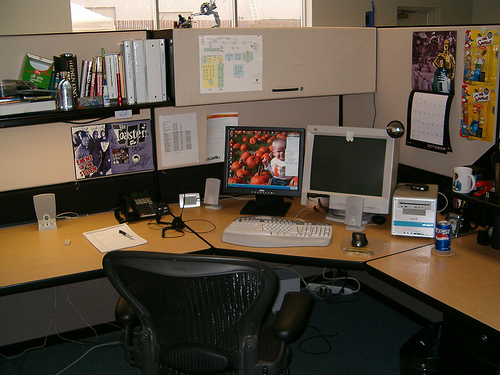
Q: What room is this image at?
A: It is at the office.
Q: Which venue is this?
A: This is an office.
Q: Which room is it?
A: It is an office.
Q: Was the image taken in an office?
A: Yes, it was taken in an office.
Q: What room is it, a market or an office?
A: It is an office.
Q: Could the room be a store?
A: No, it is an office.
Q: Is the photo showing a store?
A: No, the picture is showing an office.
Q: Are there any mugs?
A: Yes, there is a mug.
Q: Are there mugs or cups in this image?
A: Yes, there is a mug.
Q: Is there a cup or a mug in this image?
A: Yes, there is a mug.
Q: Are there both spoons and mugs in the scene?
A: No, there is a mug but no spoons.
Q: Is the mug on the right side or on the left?
A: The mug is on the right of the image.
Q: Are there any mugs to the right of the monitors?
A: Yes, there is a mug to the right of the monitors.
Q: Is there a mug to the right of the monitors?
A: Yes, there is a mug to the right of the monitors.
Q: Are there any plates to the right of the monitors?
A: No, there is a mug to the right of the monitors.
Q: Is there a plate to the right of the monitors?
A: No, there is a mug to the right of the monitors.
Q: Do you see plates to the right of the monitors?
A: No, there is a mug to the right of the monitors.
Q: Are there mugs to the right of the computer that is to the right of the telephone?
A: Yes, there is a mug to the right of the computer.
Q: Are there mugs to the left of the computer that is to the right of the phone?
A: No, the mug is to the right of the computer.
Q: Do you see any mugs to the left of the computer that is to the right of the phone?
A: No, the mug is to the right of the computer.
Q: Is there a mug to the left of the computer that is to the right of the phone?
A: No, the mug is to the right of the computer.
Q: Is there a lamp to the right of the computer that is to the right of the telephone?
A: No, there is a mug to the right of the computer.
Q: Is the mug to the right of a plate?
A: No, the mug is to the right of the computer.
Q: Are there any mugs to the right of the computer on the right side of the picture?
A: Yes, there is a mug to the right of the computer.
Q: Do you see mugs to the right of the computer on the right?
A: Yes, there is a mug to the right of the computer.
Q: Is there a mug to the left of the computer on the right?
A: No, the mug is to the right of the computer.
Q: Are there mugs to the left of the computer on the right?
A: No, the mug is to the right of the computer.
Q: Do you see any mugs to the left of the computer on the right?
A: No, the mug is to the right of the computer.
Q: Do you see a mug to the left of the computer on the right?
A: No, the mug is to the right of the computer.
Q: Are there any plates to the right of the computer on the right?
A: No, there is a mug to the right of the computer.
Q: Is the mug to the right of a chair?
A: No, the mug is to the right of a computer.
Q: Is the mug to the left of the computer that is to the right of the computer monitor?
A: No, the mug is to the right of the computer.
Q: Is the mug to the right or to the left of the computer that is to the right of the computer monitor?
A: The mug is to the right of the computer.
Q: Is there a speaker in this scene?
A: Yes, there is a speaker.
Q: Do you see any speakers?
A: Yes, there is a speaker.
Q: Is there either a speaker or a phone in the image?
A: Yes, there is a speaker.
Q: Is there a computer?
A: Yes, there is a computer.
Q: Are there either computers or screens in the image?
A: Yes, there is a computer.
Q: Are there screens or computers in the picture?
A: Yes, there is a computer.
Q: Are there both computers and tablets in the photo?
A: No, there is a computer but no tablets.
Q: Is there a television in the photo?
A: No, there are no televisions.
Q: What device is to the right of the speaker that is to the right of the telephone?
A: The device is a computer.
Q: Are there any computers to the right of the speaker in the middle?
A: Yes, there is a computer to the right of the speaker.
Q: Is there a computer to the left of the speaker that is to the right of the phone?
A: No, the computer is to the right of the speaker.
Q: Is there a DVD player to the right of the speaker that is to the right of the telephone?
A: No, there is a computer to the right of the speaker.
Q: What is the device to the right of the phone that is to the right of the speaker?
A: The device is a computer.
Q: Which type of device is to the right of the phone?
A: The device is a computer.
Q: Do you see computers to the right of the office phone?
A: Yes, there is a computer to the right of the phone.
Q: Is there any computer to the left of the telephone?
A: No, the computer is to the right of the telephone.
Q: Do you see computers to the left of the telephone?
A: No, the computer is to the right of the telephone.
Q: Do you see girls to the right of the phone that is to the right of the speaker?
A: No, there is a computer to the right of the phone.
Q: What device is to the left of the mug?
A: The device is a computer.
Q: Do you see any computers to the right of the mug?
A: No, the computer is to the left of the mug.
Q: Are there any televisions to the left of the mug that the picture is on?
A: No, there is a computer to the left of the mug.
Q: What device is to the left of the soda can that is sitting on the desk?
A: The device is a computer.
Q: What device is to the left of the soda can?
A: The device is a computer.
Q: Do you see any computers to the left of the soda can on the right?
A: Yes, there is a computer to the left of the soda can.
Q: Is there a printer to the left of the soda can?
A: No, there is a computer to the left of the soda can.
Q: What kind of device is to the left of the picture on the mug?
A: The device is a computer.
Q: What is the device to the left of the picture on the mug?
A: The device is a computer.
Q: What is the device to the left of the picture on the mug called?
A: The device is a computer.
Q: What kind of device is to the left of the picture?
A: The device is a computer.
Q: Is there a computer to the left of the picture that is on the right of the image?
A: Yes, there is a computer to the left of the picture.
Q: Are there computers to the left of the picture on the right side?
A: Yes, there is a computer to the left of the picture.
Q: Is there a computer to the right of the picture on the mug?
A: No, the computer is to the left of the picture.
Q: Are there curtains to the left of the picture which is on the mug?
A: No, there is a computer to the left of the picture.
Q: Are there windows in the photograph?
A: Yes, there is a window.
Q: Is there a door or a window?
A: Yes, there is a window.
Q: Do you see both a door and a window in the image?
A: No, there is a window but no doors.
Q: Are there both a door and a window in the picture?
A: No, there is a window but no doors.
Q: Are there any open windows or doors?
A: Yes, there is an open window.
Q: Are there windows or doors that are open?
A: Yes, the window is open.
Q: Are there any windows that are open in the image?
A: Yes, there is an open window.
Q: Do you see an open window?
A: Yes, there is an open window.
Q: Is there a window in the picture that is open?
A: Yes, there is a window that is open.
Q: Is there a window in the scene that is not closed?
A: Yes, there is a open window.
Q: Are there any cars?
A: No, there are no cars.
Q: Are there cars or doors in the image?
A: No, there are no cars or doors.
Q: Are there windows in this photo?
A: Yes, there is a window.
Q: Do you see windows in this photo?
A: Yes, there is a window.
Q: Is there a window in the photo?
A: Yes, there is a window.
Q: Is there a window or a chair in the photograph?
A: Yes, there is a window.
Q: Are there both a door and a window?
A: No, there is a window but no doors.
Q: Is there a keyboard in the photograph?
A: Yes, there is a keyboard.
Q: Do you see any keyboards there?
A: Yes, there is a keyboard.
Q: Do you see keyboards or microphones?
A: Yes, there is a keyboard.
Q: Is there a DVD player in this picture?
A: No, there are no DVD players.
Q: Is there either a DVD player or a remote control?
A: No, there are no DVD players or remote controls.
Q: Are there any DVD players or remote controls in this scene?
A: No, there are no DVD players or remote controls.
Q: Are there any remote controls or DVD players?
A: No, there are no DVD players or remote controls.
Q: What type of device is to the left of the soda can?
A: The device is a keyboard.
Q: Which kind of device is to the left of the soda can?
A: The device is a keyboard.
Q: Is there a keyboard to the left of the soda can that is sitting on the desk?
A: Yes, there is a keyboard to the left of the soda can.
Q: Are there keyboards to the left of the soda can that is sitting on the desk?
A: Yes, there is a keyboard to the left of the soda can.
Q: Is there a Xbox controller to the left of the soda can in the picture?
A: No, there is a keyboard to the left of the soda can.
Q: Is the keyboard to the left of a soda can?
A: Yes, the keyboard is to the left of a soda can.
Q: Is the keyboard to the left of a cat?
A: No, the keyboard is to the left of a soda can.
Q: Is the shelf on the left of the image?
A: Yes, the shelf is on the left of the image.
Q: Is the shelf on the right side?
A: No, the shelf is on the left of the image.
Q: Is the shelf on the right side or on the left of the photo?
A: The shelf is on the left of the image.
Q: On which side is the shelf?
A: The shelf is on the left of the image.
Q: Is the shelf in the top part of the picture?
A: Yes, the shelf is in the top of the image.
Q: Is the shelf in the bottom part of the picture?
A: No, the shelf is in the top of the image.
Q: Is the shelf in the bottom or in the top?
A: The shelf is in the top of the image.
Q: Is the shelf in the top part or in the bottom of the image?
A: The shelf is in the top of the image.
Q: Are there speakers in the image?
A: Yes, there is a speaker.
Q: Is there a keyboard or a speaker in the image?
A: Yes, there is a speaker.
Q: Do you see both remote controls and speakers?
A: No, there is a speaker but no remote controls.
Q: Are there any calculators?
A: No, there are no calculators.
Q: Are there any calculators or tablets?
A: No, there are no calculators or tablets.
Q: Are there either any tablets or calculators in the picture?
A: No, there are no calculators or tablets.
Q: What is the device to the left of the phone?
A: The device is a speaker.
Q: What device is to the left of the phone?
A: The device is a speaker.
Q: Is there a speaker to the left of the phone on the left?
A: Yes, there is a speaker to the left of the telephone.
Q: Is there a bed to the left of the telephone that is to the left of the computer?
A: No, there is a speaker to the left of the phone.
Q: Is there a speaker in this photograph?
A: Yes, there is a speaker.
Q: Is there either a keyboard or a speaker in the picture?
A: Yes, there is a speaker.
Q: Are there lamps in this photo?
A: No, there are no lamps.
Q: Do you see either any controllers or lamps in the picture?
A: No, there are no lamps or controllers.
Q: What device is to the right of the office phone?
A: The device is a speaker.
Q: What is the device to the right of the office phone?
A: The device is a speaker.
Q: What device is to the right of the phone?
A: The device is a speaker.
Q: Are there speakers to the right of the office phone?
A: Yes, there is a speaker to the right of the telephone.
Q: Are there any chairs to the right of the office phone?
A: No, there is a speaker to the right of the phone.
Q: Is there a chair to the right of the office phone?
A: No, there is a speaker to the right of the phone.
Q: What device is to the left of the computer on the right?
A: The device is a speaker.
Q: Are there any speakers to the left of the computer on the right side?
A: Yes, there is a speaker to the left of the computer.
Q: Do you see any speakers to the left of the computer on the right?
A: Yes, there is a speaker to the left of the computer.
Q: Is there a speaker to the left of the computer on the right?
A: Yes, there is a speaker to the left of the computer.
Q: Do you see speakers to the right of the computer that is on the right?
A: No, the speaker is to the left of the computer.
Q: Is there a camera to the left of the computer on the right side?
A: No, there is a speaker to the left of the computer.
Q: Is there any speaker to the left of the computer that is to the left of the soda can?
A: Yes, there is a speaker to the left of the computer.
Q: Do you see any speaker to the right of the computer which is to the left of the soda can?
A: No, the speaker is to the left of the computer.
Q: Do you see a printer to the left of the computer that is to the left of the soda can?
A: No, there is a speaker to the left of the computer.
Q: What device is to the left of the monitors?
A: The device is a speaker.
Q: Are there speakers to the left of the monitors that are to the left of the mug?
A: Yes, there is a speaker to the left of the monitors.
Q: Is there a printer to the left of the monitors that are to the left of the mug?
A: No, there is a speaker to the left of the monitors.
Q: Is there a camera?
A: No, there are no cameras.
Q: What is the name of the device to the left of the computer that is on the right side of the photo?
A: The device is a computer monitor.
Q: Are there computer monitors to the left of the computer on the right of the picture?
A: Yes, there is a computer monitor to the left of the computer.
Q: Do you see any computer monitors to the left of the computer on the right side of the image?
A: Yes, there is a computer monitor to the left of the computer.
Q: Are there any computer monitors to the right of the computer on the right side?
A: No, the computer monitor is to the left of the computer.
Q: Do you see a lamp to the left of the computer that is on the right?
A: No, there is a computer monitor to the left of the computer.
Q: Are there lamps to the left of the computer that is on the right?
A: No, there is a computer monitor to the left of the computer.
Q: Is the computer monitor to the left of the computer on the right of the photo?
A: Yes, the computer monitor is to the left of the computer.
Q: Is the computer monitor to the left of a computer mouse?
A: No, the computer monitor is to the left of the computer.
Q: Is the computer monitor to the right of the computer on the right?
A: No, the computer monitor is to the left of the computer.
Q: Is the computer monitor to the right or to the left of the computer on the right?
A: The computer monitor is to the left of the computer.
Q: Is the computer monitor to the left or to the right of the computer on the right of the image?
A: The computer monitor is to the left of the computer.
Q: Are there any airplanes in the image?
A: No, there are no airplanes.